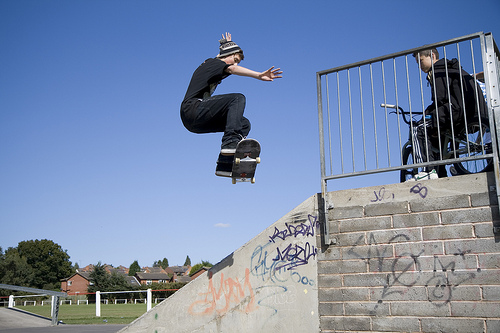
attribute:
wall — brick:
[198, 196, 499, 321]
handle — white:
[374, 94, 398, 111]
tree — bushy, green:
[3, 234, 71, 306]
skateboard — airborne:
[222, 137, 272, 187]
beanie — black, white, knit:
[213, 32, 242, 57]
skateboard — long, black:
[235, 139, 260, 181]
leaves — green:
[28, 241, 54, 266]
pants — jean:
[179, 90, 251, 145]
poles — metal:
[324, 40, 480, 174]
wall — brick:
[320, 171, 498, 331]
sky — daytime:
[3, 2, 485, 266]